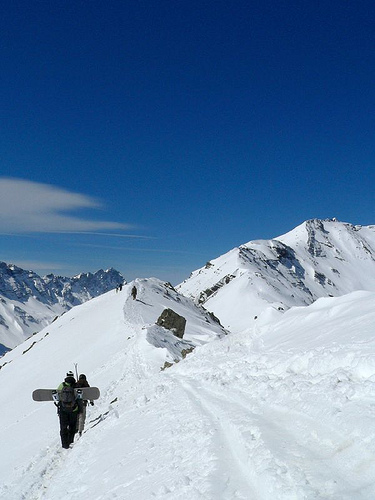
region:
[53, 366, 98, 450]
these are two men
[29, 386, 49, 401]
this is a skate board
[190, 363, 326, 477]
this is the snow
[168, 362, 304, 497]
the snow is white in color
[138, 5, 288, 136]
this is the sky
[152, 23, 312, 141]
the sky is blue in color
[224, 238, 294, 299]
this is the mountain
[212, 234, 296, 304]
the snow is white in color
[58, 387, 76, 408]
this is a bag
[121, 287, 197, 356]
grey boulder on mountain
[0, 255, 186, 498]
people walking on side of mountain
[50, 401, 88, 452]
person wearing black pants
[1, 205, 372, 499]
mountain covered in snow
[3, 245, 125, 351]
second mountain in background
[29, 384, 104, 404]
person holding grey snowboard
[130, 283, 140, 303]
person wearing all black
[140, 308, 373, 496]
set of tracks in snow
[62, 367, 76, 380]
person wearing winter hat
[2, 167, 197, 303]
white cloud in background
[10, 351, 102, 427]
People hiking up a mountain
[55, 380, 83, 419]
person wearing a backpack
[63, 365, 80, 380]
Man wearing a white and black hat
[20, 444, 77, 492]
foot prints in the snow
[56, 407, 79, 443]
man wearing black pants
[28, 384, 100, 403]
man holding a snow board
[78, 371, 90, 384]
man wearing a black hat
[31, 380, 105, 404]
man carrying a snow board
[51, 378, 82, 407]
man wearing a green jacket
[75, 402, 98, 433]
person wearing white pants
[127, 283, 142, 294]
Person wearing black coat.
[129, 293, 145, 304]
Person wearing black pants.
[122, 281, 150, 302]
Person walking up mountain side.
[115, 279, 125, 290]
Person wearing dark clothing.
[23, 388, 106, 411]
Person carrying snowboard.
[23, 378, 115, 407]
Snowboard is gray in color.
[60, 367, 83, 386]
Person wearing white and black hat.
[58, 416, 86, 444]
Person wearing black pants.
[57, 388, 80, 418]
Back pack on person's back.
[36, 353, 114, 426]
People walking up side of mountain.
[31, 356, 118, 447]
two men in ice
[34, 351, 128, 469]
two men walking in ice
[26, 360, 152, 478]
two person standing in ice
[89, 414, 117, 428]
shadow of the person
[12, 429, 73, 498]
foot prints of the persons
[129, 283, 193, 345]
a mountain in ice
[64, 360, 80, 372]
a man holidng stick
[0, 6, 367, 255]
a beautiful view of sky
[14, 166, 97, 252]
a white cloud in sky